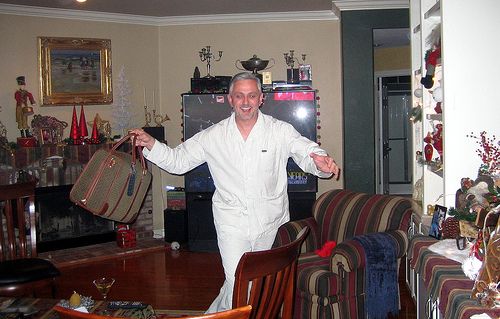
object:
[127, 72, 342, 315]
man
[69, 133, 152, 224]
suitcase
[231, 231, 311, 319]
chair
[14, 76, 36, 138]
solider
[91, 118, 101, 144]
trees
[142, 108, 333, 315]
robe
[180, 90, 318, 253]
tv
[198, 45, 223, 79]
candlesticks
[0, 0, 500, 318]
living room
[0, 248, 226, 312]
floor